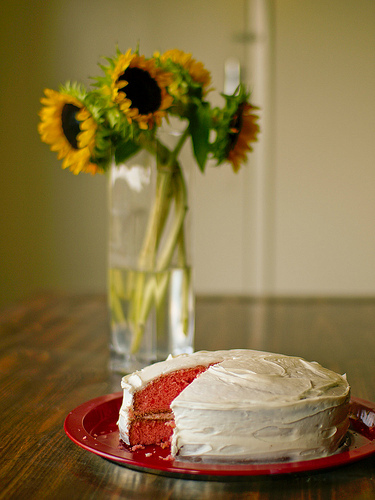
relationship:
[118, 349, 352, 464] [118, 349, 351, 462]
cake has icing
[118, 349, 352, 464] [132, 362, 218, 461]
cake has missing piece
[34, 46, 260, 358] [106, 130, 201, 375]
sunflowers in vase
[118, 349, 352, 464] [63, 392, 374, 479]
cake on plate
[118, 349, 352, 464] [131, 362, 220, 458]
cake has interior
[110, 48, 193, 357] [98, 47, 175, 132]
sunflower has head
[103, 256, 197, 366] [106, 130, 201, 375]
water in vase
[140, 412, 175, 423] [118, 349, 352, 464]
frosting in cake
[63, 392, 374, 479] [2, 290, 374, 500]
plate on top of table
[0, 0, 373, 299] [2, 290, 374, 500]
wall behind table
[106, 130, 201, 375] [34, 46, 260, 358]
vase filled sunflowers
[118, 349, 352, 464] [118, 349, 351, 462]
cake covered with icing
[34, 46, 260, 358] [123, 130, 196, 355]
sunflowers have stem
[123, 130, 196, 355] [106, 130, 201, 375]
stem in vase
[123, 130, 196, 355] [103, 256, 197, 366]
stem in water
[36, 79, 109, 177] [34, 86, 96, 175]
sunflower has petals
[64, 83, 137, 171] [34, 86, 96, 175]
leaves under petals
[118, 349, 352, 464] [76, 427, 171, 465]
cake has crumbs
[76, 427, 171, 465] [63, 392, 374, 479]
crumbs on plate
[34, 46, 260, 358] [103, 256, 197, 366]
sunflowers in water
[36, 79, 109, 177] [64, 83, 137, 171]
sunflower has leaves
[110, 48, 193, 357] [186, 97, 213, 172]
sunflower has leaf